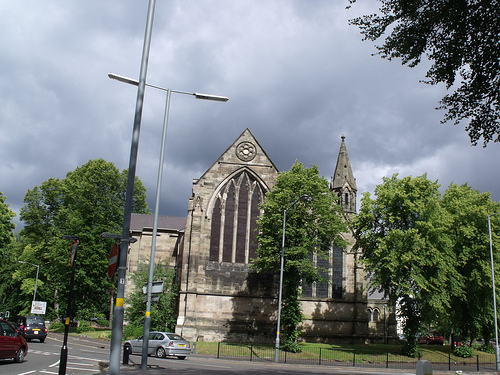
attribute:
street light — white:
[194, 92, 228, 103]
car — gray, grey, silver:
[125, 332, 191, 360]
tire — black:
[17, 348, 27, 363]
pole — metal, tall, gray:
[103, 3, 156, 374]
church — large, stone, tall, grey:
[130, 129, 417, 345]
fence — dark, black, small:
[195, 343, 499, 371]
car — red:
[0, 317, 28, 363]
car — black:
[14, 314, 46, 342]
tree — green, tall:
[258, 160, 346, 355]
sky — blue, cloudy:
[0, 0, 499, 229]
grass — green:
[195, 339, 495, 363]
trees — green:
[257, 163, 499, 361]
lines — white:
[20, 352, 109, 374]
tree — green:
[24, 160, 148, 327]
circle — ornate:
[236, 140, 255, 163]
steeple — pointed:
[330, 132, 356, 189]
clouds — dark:
[0, 10, 459, 215]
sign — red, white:
[105, 242, 120, 276]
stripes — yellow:
[64, 293, 153, 327]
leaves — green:
[347, 3, 499, 139]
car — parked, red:
[421, 331, 443, 345]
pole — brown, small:
[59, 240, 82, 375]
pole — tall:
[105, 72, 228, 368]